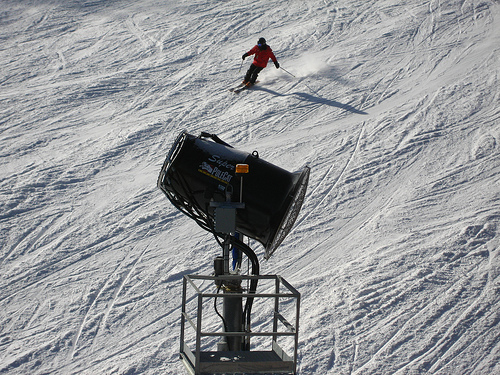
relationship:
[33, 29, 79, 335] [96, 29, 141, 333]
ground has snow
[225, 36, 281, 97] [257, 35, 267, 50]
man has helmet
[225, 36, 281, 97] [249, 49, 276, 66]
man has jacket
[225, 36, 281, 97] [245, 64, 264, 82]
man has pants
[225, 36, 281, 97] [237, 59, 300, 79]
man has poles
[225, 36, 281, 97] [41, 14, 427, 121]
man on mountain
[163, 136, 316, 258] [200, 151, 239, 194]
light has letters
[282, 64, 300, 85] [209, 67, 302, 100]
pole for skiing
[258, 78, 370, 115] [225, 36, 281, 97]
shadow of man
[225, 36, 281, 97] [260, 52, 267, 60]
man wearing red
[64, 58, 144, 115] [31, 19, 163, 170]
ice in heap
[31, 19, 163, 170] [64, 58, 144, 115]
heap of ice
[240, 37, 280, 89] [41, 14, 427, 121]
man on mountain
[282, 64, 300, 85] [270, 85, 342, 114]
pole in snow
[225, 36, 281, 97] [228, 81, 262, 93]
man has skis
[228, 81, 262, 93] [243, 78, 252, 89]
skis on feet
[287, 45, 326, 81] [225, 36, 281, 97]
snow behind man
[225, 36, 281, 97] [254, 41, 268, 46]
man has mask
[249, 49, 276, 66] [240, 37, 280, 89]
jacket on man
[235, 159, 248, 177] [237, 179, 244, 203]
light on pole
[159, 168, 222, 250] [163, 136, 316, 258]
wires for light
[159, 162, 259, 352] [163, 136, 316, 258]
wires for light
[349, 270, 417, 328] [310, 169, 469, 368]
lines in snow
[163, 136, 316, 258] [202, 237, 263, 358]
light on mast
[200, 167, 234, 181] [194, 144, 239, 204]
brand on surface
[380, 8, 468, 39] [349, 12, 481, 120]
imprints in snow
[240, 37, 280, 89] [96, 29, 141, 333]
man on snow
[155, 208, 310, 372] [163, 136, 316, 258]
stand for light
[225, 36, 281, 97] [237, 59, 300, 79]
man holding poles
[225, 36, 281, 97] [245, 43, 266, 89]
man has snowsuit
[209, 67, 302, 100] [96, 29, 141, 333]
skiing in snow